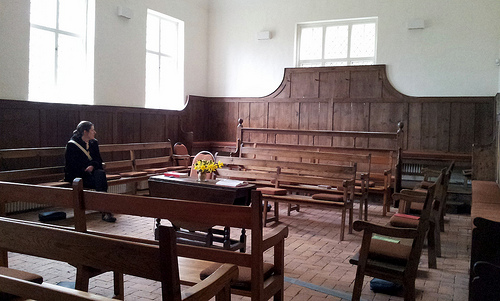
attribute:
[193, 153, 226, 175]
flowers — yellow, bright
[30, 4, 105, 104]
window — frame, white, paned, large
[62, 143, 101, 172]
jacket — black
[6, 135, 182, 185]
bench — brown, wooden, long, dark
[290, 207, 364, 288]
floor — red, bricked, tiled, brown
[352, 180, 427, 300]
chair — wood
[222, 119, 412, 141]
railing — wood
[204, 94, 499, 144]
wall — wood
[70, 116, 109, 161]
person — sitting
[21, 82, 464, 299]
church — interior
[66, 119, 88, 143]
hair — brown